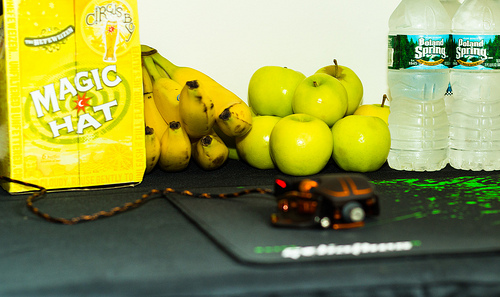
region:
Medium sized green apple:
[237, 56, 312, 112]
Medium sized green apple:
[265, 106, 330, 181]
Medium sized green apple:
[232, 110, 287, 175]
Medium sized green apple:
[320, 90, 410, 185]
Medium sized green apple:
[310, 50, 360, 111]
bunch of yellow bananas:
[115, 10, 261, 191]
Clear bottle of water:
[385, 0, 456, 180]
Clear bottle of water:
[445, 0, 495, 175]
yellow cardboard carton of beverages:
[2, 0, 159, 205]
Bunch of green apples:
[209, 33, 421, 183]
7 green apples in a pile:
[237, 59, 387, 179]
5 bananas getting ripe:
[135, 45, 252, 172]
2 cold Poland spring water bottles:
[386, 1, 496, 169]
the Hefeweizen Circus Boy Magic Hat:
[0, 1, 146, 195]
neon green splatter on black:
[379, 171, 496, 237]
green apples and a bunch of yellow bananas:
[139, 40, 387, 177]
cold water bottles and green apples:
[245, 0, 497, 175]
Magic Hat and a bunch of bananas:
[0, 0, 252, 192]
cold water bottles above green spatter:
[384, 1, 494, 232]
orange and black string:
[13, 191, 227, 227]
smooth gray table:
[53, 239, 167, 262]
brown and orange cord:
[57, 190, 138, 225]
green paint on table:
[426, 174, 491, 213]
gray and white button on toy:
[333, 197, 366, 231]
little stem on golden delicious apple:
[330, 55, 353, 74]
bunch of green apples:
[251, 64, 386, 157]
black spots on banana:
[210, 102, 242, 134]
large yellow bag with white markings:
[4, 5, 163, 233]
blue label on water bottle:
[397, 32, 490, 61]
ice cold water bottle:
[391, 5, 457, 182]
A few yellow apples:
[241, 51, 386, 176]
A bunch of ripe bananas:
[141, 40, 251, 175]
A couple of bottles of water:
[382, 0, 497, 175]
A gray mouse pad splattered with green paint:
[160, 170, 495, 265]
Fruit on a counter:
[140, 15, 380, 185]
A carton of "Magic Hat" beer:
[0, 0, 145, 190]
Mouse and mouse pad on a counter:
[155, 165, 495, 285]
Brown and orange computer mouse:
[260, 165, 386, 235]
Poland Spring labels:
[380, 25, 495, 70]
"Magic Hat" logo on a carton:
[25, 60, 125, 140]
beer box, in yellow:
[0, 3, 150, 198]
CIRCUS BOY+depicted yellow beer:
[83, 1, 138, 66]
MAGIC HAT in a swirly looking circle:
[18, 60, 132, 150]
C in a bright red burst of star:
[69, 91, 95, 117]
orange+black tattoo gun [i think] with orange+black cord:
[0, 170, 387, 240]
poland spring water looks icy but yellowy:
[386, 1, 498, 175]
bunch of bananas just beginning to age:
[145, 42, 257, 170]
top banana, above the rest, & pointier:
[143, 48, 218, 135]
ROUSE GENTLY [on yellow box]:
[62, 166, 132, 190]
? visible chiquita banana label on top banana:
[172, 91, 189, 104]